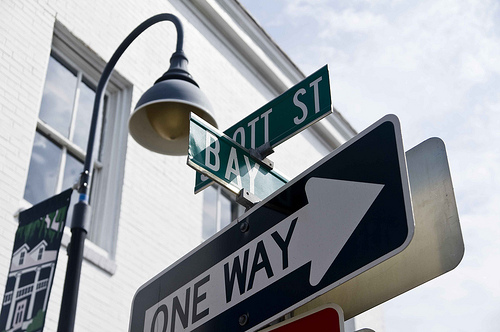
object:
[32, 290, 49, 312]
window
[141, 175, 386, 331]
arrow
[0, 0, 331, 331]
wall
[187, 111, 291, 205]
sign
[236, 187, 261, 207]
pole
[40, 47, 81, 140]
pane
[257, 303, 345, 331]
sign show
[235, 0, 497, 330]
sky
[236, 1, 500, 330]
cloud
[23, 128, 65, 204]
pane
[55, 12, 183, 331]
pole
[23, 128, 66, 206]
window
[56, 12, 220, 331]
lamp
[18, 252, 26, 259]
window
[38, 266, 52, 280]
window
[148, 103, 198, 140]
light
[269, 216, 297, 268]
letter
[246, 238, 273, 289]
letter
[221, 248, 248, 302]
letter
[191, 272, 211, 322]
letter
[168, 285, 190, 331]
letter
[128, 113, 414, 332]
sign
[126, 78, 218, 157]
globe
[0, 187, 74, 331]
banner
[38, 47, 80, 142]
window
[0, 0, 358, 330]
brick building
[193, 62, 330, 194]
sign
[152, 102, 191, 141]
bulb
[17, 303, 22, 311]
window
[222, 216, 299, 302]
word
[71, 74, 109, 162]
pane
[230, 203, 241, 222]
pole